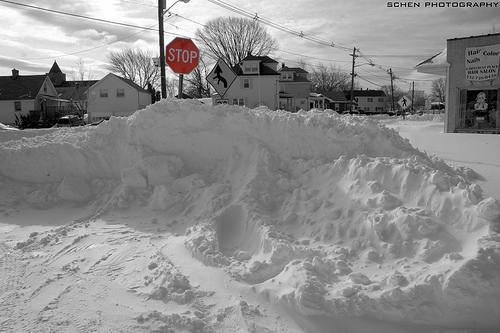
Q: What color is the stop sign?
A: Red.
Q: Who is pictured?
A: No one.